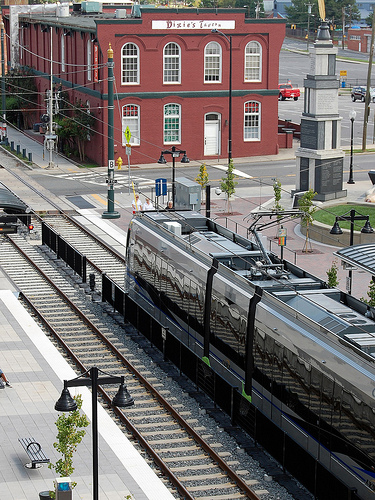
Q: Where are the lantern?
A: At station.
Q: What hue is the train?
A: Silver.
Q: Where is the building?
A: The corner.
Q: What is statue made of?
A: Concrete.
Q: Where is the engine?
A: On train.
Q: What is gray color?
A: Engine.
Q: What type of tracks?
A: Train.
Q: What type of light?
A: Street.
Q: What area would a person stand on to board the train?
A: The boarding platform.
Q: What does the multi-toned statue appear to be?
A: A memorial.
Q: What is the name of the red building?
A: Dixie's Tavern.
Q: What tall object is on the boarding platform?
A: A black light post.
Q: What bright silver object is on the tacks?
A: A train.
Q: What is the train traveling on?
A: Train tracks.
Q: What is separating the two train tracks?
A: A black wrought iron fence.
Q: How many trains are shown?
A: One.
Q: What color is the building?
A: Red.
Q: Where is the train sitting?
A: Tracks.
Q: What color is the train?
A: Silver.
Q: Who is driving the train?
A: Conductor.